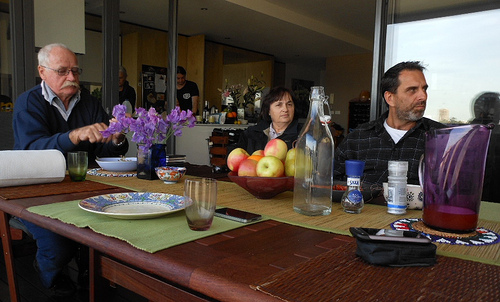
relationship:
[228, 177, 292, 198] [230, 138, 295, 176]
bowl has fruit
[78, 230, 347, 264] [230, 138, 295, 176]
counter has apples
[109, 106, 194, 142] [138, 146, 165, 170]
flowers are in vase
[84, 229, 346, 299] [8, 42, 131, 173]
table has man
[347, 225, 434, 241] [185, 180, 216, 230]
cell phone next to glass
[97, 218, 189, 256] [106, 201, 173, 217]
placemat under plate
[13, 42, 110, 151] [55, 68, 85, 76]
man wearing glasses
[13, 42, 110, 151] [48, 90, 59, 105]
person wearing shirt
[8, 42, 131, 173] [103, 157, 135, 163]
man eating meal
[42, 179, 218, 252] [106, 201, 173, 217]
placesetting has plate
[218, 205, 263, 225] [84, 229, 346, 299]
cell phone on table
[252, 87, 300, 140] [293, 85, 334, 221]
woman with bottle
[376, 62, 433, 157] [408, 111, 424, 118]
man has beard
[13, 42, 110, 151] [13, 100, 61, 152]
man has sweater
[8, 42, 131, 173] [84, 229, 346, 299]
man siting at table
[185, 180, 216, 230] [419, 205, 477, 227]
glass for drinks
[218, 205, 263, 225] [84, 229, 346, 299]
phone on table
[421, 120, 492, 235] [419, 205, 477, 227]
pitcher has juice